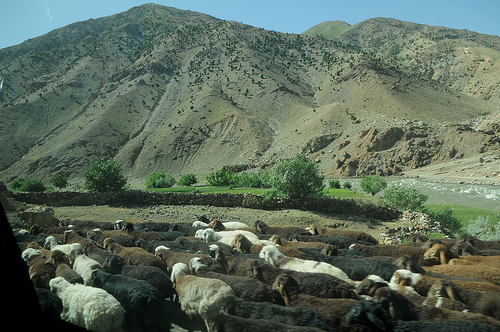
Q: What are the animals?
A: Sheep.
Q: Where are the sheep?
A: In front of the mountain.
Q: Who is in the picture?
A: No one.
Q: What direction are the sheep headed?
A: Left.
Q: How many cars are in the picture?
A: None.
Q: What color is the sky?
A: Blue.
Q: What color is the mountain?
A: Brown.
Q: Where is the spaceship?
A: Nowhere.